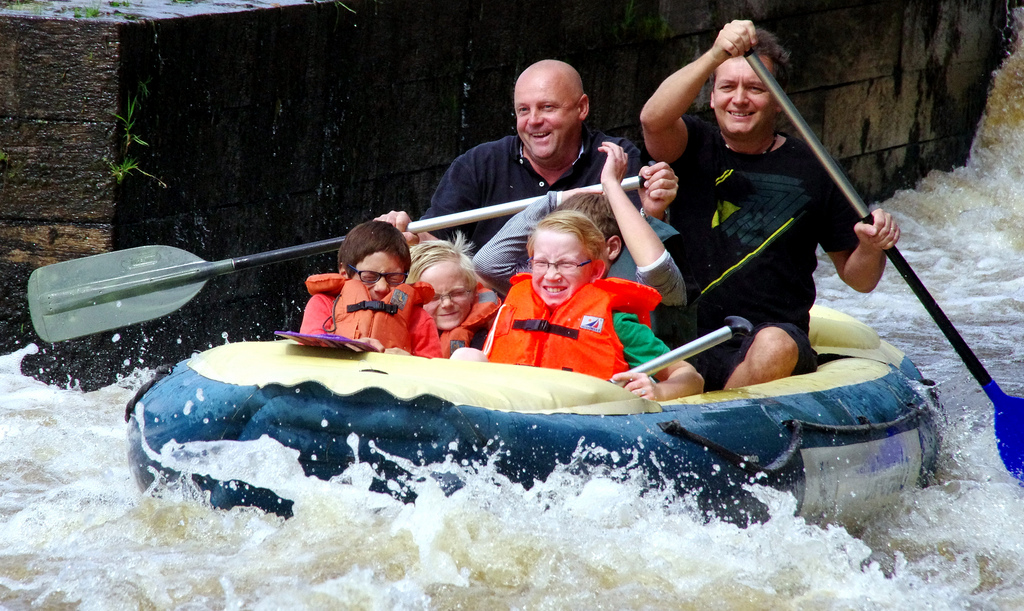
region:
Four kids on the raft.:
[326, 203, 684, 391]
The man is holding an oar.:
[767, 61, 1021, 431]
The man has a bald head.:
[503, 54, 589, 103]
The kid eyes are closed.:
[408, 281, 489, 313]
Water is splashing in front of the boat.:
[87, 414, 680, 608]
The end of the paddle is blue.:
[973, 380, 1022, 472]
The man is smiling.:
[489, 124, 575, 148]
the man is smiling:
[507, 67, 585, 165]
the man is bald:
[522, 65, 583, 160]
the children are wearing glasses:
[365, 253, 590, 283]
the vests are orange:
[348, 288, 644, 381]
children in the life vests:
[327, 266, 656, 380]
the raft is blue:
[133, 381, 915, 524]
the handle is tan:
[377, 163, 692, 255]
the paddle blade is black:
[38, 234, 257, 374]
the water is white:
[57, 507, 883, 591]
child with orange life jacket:
[448, 209, 718, 406]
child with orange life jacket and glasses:
[287, 216, 443, 366]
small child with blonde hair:
[397, 232, 506, 359]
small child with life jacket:
[399, 232, 499, 357]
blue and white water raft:
[124, 294, 956, 545]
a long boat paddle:
[24, 164, 666, 349]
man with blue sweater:
[365, 54, 683, 289]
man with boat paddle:
[726, 14, 1021, 485]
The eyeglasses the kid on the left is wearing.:
[527, 256, 594, 282]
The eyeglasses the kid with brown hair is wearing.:
[353, 268, 404, 285]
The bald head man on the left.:
[432, 53, 676, 238]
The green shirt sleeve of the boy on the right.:
[612, 307, 664, 369]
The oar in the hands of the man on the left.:
[17, 153, 657, 344]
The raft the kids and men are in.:
[133, 303, 944, 557]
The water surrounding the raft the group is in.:
[0, 81, 1018, 605]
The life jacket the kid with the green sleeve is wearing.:
[492, 274, 660, 377]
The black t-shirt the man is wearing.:
[667, 105, 857, 325]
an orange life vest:
[490, 266, 659, 380]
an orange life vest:
[304, 266, 431, 343]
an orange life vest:
[435, 279, 496, 350]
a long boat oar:
[32, 174, 643, 345]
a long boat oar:
[743, 50, 1022, 483]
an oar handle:
[618, 316, 749, 377]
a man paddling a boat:
[636, 21, 1022, 483]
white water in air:
[175, 396, 201, 423]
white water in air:
[107, 333, 126, 350]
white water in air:
[112, 296, 125, 310]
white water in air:
[218, 327, 231, 341]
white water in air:
[11, 334, 24, 348]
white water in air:
[845, 480, 858, 503]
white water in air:
[709, 457, 720, 470]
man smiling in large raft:
[635, 15, 901, 393]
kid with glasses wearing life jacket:
[480, 210, 709, 411]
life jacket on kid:
[478, 267, 666, 375]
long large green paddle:
[27, 178, 644, 341]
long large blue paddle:
[741, 42, 1020, 488]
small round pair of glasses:
[353, 267, 407, 284]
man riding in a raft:
[428, 59, 634, 262]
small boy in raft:
[298, 223, 442, 359]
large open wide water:
[0, 68, 1023, 607]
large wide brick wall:
[1, 2, 1014, 394]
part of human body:
[499, 45, 598, 182]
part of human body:
[702, 32, 797, 138]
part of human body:
[331, 222, 421, 298]